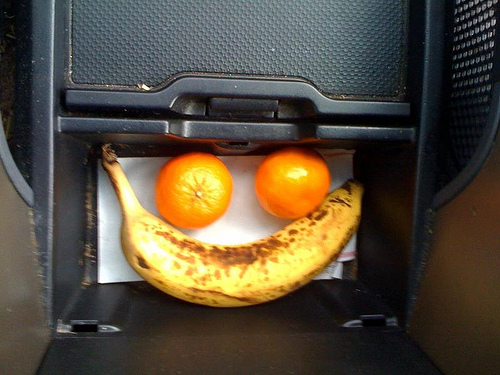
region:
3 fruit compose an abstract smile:
[98, 141, 363, 306]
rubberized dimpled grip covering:
[75, 3, 397, 87]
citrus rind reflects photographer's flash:
[177, 167, 309, 210]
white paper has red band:
[338, 250, 354, 259]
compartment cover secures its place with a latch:
[205, 92, 280, 118]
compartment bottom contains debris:
[82, 145, 93, 280]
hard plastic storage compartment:
[33, 2, 439, 372]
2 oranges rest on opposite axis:
[155, 153, 328, 229]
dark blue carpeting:
[2, 0, 29, 117]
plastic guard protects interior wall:
[432, 0, 497, 198]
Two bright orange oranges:
[152, 148, 329, 227]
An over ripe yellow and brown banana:
[101, 147, 360, 309]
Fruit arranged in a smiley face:
[99, 138, 362, 307]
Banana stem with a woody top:
[99, 144, 144, 215]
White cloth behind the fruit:
[92, 145, 355, 283]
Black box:
[27, 1, 444, 331]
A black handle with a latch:
[165, 75, 325, 123]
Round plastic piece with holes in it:
[438, 0, 498, 207]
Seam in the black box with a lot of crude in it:
[69, 72, 409, 104]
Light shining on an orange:
[177, 169, 222, 216]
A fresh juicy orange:
[263, 150, 318, 210]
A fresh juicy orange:
[160, 159, 235, 231]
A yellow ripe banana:
[97, 149, 366, 289]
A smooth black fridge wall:
[297, 332, 424, 364]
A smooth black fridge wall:
[212, 319, 282, 366]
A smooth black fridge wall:
[97, 293, 157, 371]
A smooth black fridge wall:
[65, 173, 102, 273]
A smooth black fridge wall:
[368, 176, 396, 271]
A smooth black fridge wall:
[156, 295, 288, 330]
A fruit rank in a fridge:
[83, 149, 348, 316]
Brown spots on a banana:
[196, 245, 264, 262]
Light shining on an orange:
[280, 165, 312, 183]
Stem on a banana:
[100, 147, 135, 206]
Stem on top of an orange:
[178, 177, 224, 211]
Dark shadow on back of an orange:
[284, 147, 321, 162]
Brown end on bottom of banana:
[344, 180, 366, 203]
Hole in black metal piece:
[56, 320, 116, 336]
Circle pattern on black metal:
[76, 70, 160, 87]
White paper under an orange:
[231, 157, 255, 234]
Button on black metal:
[200, 94, 285, 125]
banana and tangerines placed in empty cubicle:
[55, 117, 422, 349]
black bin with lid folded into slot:
[35, 72, 425, 352]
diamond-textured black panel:
[66, 1, 401, 108]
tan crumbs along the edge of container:
[81, 155, 91, 286]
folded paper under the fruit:
[86, 150, 356, 290]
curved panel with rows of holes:
[432, 0, 490, 200]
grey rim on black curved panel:
[0, 0, 35, 210]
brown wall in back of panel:
[0, 175, 40, 370]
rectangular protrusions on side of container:
[65, 315, 387, 340]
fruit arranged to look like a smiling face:
[85, 145, 362, 310]